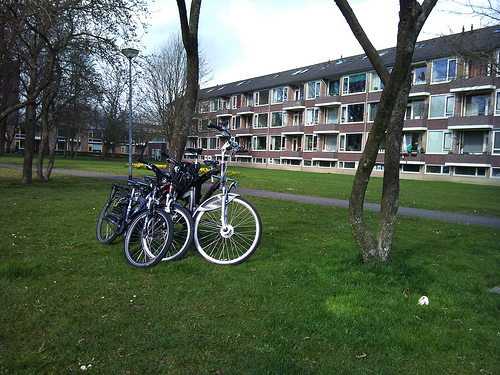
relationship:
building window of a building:
[341, 72, 367, 96] [178, 39, 478, 212]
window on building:
[340, 133, 345, 150] [153, 21, 498, 179]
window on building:
[341, 77, 348, 94] [153, 21, 498, 179]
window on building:
[427, 130, 451, 155] [153, 21, 498, 179]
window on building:
[447, 58, 456, 79] [153, 21, 498, 179]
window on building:
[426, 93, 455, 120] [153, 21, 498, 179]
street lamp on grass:
[120, 46, 140, 181] [3, 157, 497, 371]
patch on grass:
[312, 294, 412, 330] [297, 272, 476, 354]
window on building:
[254, 87, 271, 106] [153, 21, 498, 179]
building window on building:
[340, 72, 348, 94] [153, 21, 498, 179]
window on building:
[340, 128, 365, 155] [153, 21, 498, 179]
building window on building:
[341, 72, 367, 96] [153, 21, 498, 179]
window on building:
[431, 57, 461, 87] [203, 36, 499, 182]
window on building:
[426, 93, 455, 120] [203, 36, 499, 182]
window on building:
[427, 130, 449, 155] [203, 36, 499, 182]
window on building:
[450, 88, 498, 120] [157, 20, 484, 206]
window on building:
[431, 59, 456, 81] [157, 20, 484, 206]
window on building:
[410, 62, 429, 87] [157, 20, 484, 206]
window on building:
[341, 73, 368, 95] [157, 20, 484, 206]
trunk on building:
[170, 0, 202, 170] [157, 20, 484, 206]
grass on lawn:
[3, 157, 497, 371] [3, 154, 498, 373]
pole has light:
[124, 58, 136, 175] [117, 45, 142, 60]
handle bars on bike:
[137, 152, 194, 192] [90, 134, 193, 268]